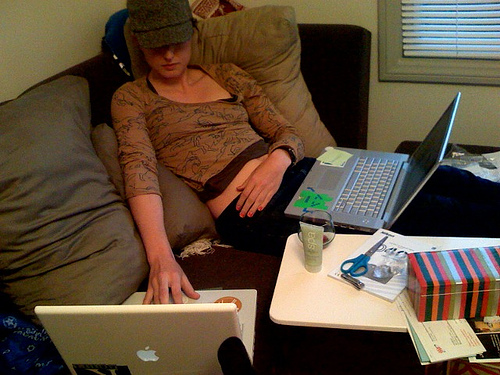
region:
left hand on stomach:
[232, 132, 301, 229]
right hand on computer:
[33, 209, 253, 374]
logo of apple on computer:
[122, 340, 183, 366]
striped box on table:
[392, 249, 499, 311]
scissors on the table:
[341, 230, 376, 286]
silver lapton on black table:
[276, 90, 451, 232]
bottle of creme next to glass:
[301, 219, 323, 286]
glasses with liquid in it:
[317, 209, 340, 254]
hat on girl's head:
[115, 0, 212, 34]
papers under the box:
[391, 248, 498, 365]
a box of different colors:
[409, 246, 496, 317]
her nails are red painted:
[232, 186, 262, 217]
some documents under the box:
[405, 315, 481, 363]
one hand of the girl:
[234, 148, 286, 215]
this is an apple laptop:
[36, 280, 258, 369]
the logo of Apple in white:
[136, 345, 158, 362]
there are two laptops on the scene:
[1, 88, 464, 374]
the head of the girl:
[124, 2, 198, 76]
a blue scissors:
[343, 233, 386, 275]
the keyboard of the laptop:
[341, 160, 391, 212]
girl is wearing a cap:
[120, 7, 210, 96]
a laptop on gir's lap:
[265, 85, 461, 247]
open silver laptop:
[281, 83, 467, 242]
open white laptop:
[24, 255, 264, 374]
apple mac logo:
[127, 340, 166, 370]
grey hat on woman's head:
[120, 1, 206, 57]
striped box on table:
[397, 235, 496, 327]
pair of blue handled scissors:
[332, 228, 394, 283]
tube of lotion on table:
[292, 213, 330, 278]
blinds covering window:
[387, 3, 498, 81]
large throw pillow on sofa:
[109, 5, 344, 175]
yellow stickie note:
[310, 139, 355, 170]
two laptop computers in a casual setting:
[28, 86, 463, 368]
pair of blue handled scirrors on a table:
[340, 234, 390, 279]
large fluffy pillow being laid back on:
[93, 0, 337, 243]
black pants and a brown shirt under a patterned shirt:
[104, 2, 487, 272]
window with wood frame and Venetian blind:
[373, 0, 497, 90]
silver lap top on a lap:
[286, 91, 462, 231]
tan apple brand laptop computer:
[30, 287, 257, 373]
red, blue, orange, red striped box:
[407, 246, 496, 323]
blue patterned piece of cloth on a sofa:
[0, 315, 58, 370]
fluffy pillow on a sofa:
[0, 68, 220, 338]